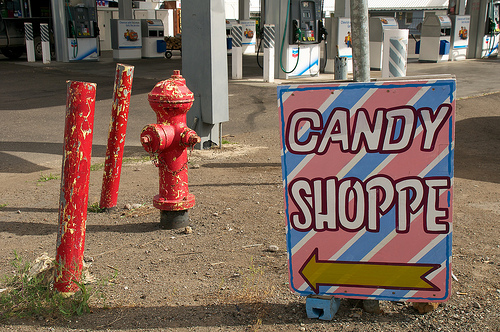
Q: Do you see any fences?
A: No, there are no fences.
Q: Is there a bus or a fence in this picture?
A: No, there are no fences or buses.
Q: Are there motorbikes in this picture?
A: No, there are no motorbikes.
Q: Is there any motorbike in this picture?
A: No, there are no motorcycles.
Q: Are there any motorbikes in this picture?
A: No, there are no motorbikes.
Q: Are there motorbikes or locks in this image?
A: No, there are no motorbikes or locks.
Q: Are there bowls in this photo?
A: No, there are no bowls.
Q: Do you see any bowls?
A: No, there are no bowls.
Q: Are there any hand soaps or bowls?
A: No, there are no bowls or hand soaps.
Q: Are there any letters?
A: Yes, there are letters.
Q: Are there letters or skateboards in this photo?
A: Yes, there are letters.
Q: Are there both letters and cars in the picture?
A: No, there are letters but no cars.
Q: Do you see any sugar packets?
A: No, there are no sugar packets.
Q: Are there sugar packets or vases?
A: No, there are no sugar packets or vases.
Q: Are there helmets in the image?
A: No, there are no helmets.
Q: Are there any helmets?
A: No, there are no helmets.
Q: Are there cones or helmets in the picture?
A: No, there are no helmets or cones.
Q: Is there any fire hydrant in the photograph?
A: Yes, there is a fire hydrant.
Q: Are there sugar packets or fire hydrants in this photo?
A: Yes, there is a fire hydrant.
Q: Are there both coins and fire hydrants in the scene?
A: No, there is a fire hydrant but no coins.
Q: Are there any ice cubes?
A: No, there are no ice cubes.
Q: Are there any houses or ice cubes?
A: No, there are no ice cubes or houses.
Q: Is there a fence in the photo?
A: No, there are no fences.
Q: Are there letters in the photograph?
A: Yes, there are letters.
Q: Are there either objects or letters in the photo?
A: Yes, there are letters.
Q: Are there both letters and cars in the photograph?
A: No, there are letters but no cars.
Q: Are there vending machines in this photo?
A: No, there are no vending machines.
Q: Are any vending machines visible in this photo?
A: No, there are no vending machines.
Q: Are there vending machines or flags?
A: No, there are no vending machines or flags.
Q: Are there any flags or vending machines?
A: No, there are no vending machines or flags.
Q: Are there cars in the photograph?
A: No, there are no cars.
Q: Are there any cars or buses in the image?
A: No, there are no cars or buses.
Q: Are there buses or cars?
A: No, there are no cars or buses.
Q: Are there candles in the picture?
A: No, there are no candles.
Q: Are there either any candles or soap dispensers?
A: No, there are no candles or soap dispensers.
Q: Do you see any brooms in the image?
A: No, there are no brooms.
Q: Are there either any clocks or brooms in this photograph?
A: No, there are no brooms or clocks.